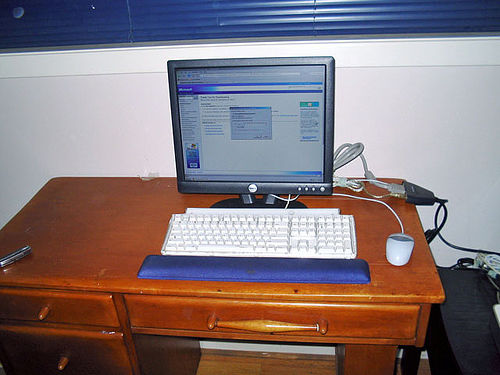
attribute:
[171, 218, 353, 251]
keyboard — white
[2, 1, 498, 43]
blinds — mini, blue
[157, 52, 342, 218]
monitor — black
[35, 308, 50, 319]
knob — wooden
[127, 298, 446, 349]
drawer — long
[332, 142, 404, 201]
cables — gray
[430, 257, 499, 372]
tower — black, plastic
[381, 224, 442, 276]
mouse — gray, plastic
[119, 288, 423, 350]
drawer — desk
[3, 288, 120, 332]
drawer — top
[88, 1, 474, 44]
window — blue, vertical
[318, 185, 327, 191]
button — silver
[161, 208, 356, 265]
keyboard — white and grey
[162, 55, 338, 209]
computer monitor — black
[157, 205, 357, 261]
keyboard — cream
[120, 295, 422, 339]
drawer — wood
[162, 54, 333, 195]
monitor — computer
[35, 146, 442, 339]
desk — old, wooden, writing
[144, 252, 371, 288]
wrist support — blue, padded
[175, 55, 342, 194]
screen — flat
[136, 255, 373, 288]
wrist pad — blue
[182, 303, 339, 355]
desk drawer — open, large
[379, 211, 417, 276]
mouse — white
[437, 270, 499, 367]
pc tower — black, desktop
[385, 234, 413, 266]
mouse — wired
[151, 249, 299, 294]
pad — wrist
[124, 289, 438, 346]
drawer — large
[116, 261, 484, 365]
drawer — wooden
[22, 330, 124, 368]
drawer — wooden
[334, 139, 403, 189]
wire — grey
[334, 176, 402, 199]
wire — grey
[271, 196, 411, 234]
wire — grey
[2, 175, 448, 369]
desk — electric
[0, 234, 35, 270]
army knife — swiss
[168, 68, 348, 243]
computer — desktop